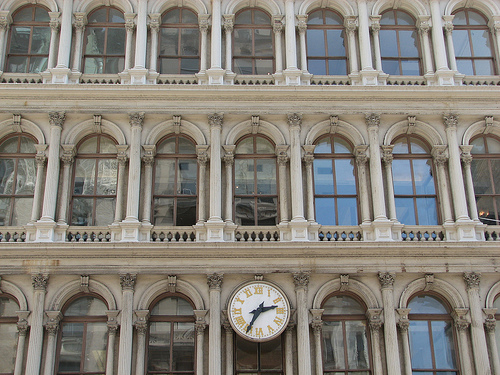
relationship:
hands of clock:
[247, 296, 279, 332] [225, 269, 307, 342]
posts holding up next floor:
[120, 115, 393, 239] [114, 3, 381, 98]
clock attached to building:
[219, 281, 297, 344] [20, 25, 490, 374]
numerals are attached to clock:
[229, 277, 291, 336] [230, 280, 297, 348]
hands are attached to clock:
[238, 298, 283, 333] [221, 276, 294, 349]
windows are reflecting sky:
[308, 115, 450, 233] [311, 148, 360, 216]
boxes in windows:
[154, 52, 199, 78] [153, 7, 204, 75]